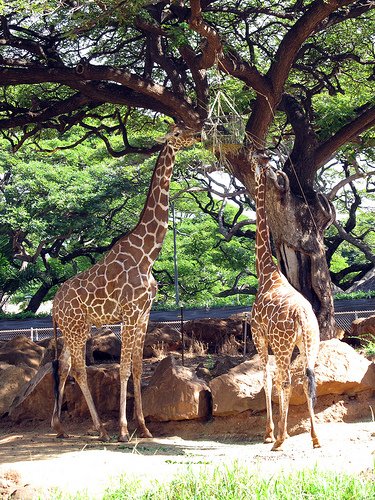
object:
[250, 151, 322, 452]
giraffe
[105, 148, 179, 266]
neck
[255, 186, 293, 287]
neck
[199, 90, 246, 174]
food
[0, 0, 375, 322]
tree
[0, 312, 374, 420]
rocks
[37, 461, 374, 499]
grass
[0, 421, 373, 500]
foreground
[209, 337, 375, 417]
rock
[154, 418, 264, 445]
shadow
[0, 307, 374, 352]
fence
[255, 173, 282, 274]
neck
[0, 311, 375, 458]
circle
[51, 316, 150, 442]
legs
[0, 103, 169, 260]
leaves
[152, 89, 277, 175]
eating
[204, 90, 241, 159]
basket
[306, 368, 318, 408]
tail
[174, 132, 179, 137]
eyes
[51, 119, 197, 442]
giraffe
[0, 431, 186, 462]
shadow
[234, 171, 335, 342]
trunk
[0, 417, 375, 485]
dirt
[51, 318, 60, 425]
tail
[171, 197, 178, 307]
pole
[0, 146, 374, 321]
background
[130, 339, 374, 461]
sun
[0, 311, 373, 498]
ground